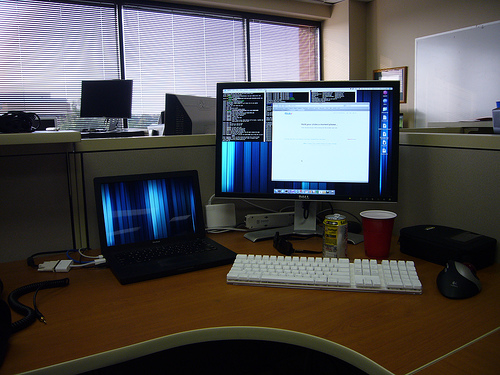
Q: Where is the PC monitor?
A: In the corner of the desk.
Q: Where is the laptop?
A: Beside the PC monitor.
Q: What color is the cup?
A: Red.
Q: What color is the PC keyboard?
A: White.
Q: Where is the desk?
A: In an office cubicle.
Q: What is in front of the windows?
A: Blinds.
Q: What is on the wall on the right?
A: White dry erase board.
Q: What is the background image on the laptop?
A: Blue stripes.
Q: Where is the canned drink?
A: Behind the white keyboard.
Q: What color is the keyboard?
A: White.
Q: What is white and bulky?
A: Keyboard.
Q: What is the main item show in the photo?
A: Computer.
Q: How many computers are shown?
A: 4.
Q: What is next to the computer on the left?
A: Laptop.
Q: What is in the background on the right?
A: Whiteboard.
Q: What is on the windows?
A: Blinds.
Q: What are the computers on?
A: Desk.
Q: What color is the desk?
A: Brown.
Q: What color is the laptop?
A: Black.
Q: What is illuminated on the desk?
A: The computer.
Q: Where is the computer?
A: On the desk.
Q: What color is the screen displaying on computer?
A: Blue, white and black.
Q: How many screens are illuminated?
A: Two.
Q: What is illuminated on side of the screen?
A: Icons.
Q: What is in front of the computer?
A: Keyboard.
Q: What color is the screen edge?
A: Black.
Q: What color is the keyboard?
A: White.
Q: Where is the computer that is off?
A: In the back.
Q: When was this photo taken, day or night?
A: During the day.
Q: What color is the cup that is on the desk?
A: Red.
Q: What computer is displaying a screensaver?
A: The laptop.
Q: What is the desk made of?
A: Wood.